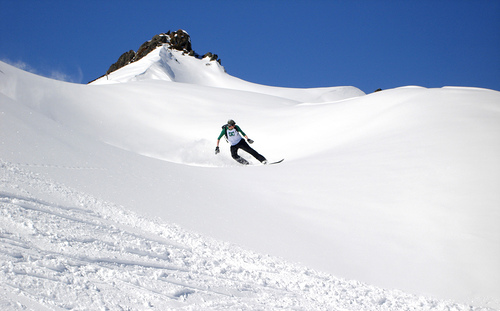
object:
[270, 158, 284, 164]
snowboard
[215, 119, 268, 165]
man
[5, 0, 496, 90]
sky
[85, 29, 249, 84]
hill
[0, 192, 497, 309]
snow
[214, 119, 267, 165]
remote control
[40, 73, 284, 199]
landscape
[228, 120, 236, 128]
hat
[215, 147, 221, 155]
gloves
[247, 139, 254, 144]
gloves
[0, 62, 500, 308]
ground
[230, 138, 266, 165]
pants